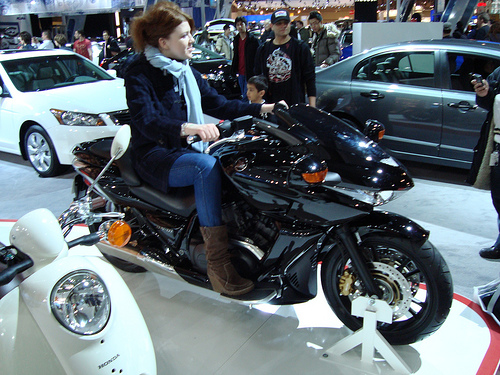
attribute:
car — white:
[1, 50, 132, 176]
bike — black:
[70, 102, 455, 347]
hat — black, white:
[270, 9, 290, 28]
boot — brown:
[196, 223, 253, 297]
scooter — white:
[0, 123, 161, 375]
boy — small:
[244, 75, 269, 107]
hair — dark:
[247, 76, 267, 92]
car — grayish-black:
[303, 36, 500, 177]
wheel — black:
[321, 229, 453, 349]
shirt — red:
[73, 40, 92, 60]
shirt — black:
[256, 38, 315, 102]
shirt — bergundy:
[236, 35, 246, 76]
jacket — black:
[230, 34, 258, 75]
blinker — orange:
[301, 167, 329, 186]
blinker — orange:
[377, 126, 385, 140]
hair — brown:
[129, 0, 194, 51]